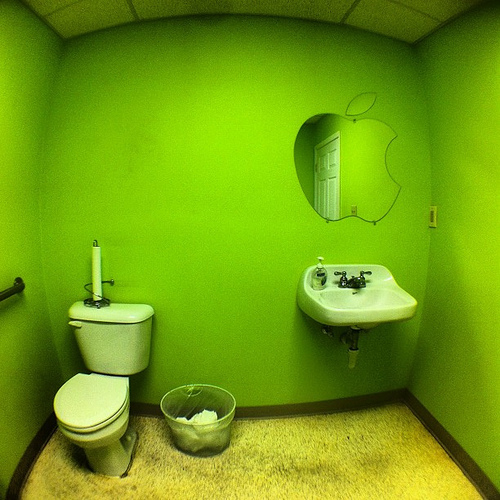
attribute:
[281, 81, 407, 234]
mirror — apple shaped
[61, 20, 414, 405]
wall — green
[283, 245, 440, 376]
sink — white, cermaic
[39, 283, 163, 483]
toilet — white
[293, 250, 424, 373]
basin — mounted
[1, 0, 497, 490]
room — neon green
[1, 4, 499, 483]
bathroom — green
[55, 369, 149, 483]
bowl — white, ceramic, porcelain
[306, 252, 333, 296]
handwash — white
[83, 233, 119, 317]
candle — large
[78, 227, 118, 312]
candle — white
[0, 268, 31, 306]
pipeline — metal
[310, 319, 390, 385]
pipeline — gray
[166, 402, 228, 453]
papers — white